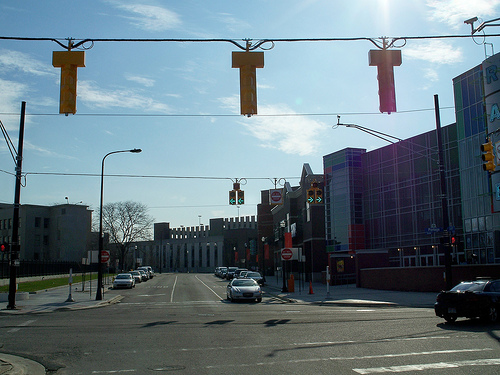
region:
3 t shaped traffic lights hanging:
[46, 38, 417, 119]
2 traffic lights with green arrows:
[220, 178, 335, 210]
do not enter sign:
[279, 245, 296, 293]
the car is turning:
[433, 275, 496, 327]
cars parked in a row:
[113, 256, 157, 301]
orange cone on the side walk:
[306, 280, 323, 305]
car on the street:
[155, 252, 316, 332]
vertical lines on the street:
[140, 259, 225, 320]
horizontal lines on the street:
[189, 325, 441, 373]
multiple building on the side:
[165, 57, 497, 283]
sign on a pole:
[260, 210, 307, 298]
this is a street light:
[211, 157, 259, 216]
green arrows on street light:
[212, 173, 254, 214]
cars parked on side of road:
[88, 233, 162, 305]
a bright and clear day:
[25, 16, 472, 370]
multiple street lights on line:
[19, 6, 487, 165]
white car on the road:
[222, 275, 267, 301]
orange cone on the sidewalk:
[282, 267, 303, 294]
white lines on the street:
[168, 272, 184, 313]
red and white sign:
[276, 244, 302, 263]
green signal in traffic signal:
[221, 192, 238, 214]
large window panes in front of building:
[365, 188, 440, 247]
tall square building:
[40, 197, 110, 269]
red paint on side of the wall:
[375, 274, 426, 291]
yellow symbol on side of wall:
[332, 256, 350, 278]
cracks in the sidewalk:
[23, 348, 60, 365]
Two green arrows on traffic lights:
[226, 187, 247, 207]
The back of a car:
[431, 276, 491, 326]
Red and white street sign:
[268, 187, 285, 205]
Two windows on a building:
[30, 212, 54, 230]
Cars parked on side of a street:
[110, 261, 156, 291]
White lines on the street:
[1, 270, 498, 370]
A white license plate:
[443, 304, 460, 316]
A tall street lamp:
[93, 145, 144, 300]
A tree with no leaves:
[90, 197, 156, 271]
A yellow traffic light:
[477, 135, 497, 174]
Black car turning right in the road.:
[433, 279, 498, 324]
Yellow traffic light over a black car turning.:
[481, 139, 496, 173]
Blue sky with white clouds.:
[1, 2, 498, 239]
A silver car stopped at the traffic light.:
[225, 277, 264, 303]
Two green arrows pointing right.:
[307, 196, 321, 203]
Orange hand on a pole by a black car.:
[450, 234, 455, 244]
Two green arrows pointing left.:
[228, 197, 243, 204]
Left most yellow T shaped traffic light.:
[50, 49, 85, 114]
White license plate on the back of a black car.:
[445, 306, 456, 315]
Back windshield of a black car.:
[448, 277, 490, 292]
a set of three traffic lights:
[52, 51, 402, 116]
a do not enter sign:
[282, 249, 295, 259]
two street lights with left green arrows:
[228, 189, 244, 206]